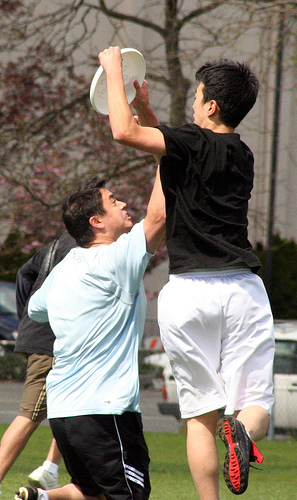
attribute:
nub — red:
[217, 417, 228, 426]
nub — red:
[222, 425, 229, 431]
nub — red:
[228, 448, 234, 454]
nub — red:
[226, 450, 235, 455]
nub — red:
[228, 458, 236, 464]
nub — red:
[226, 456, 237, 463]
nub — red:
[229, 465, 237, 472]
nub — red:
[230, 459, 236, 465]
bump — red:
[222, 419, 229, 426]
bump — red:
[223, 420, 228, 427]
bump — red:
[230, 466, 238, 472]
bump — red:
[230, 466, 237, 474]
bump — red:
[230, 473, 238, 480]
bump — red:
[229, 467, 236, 472]